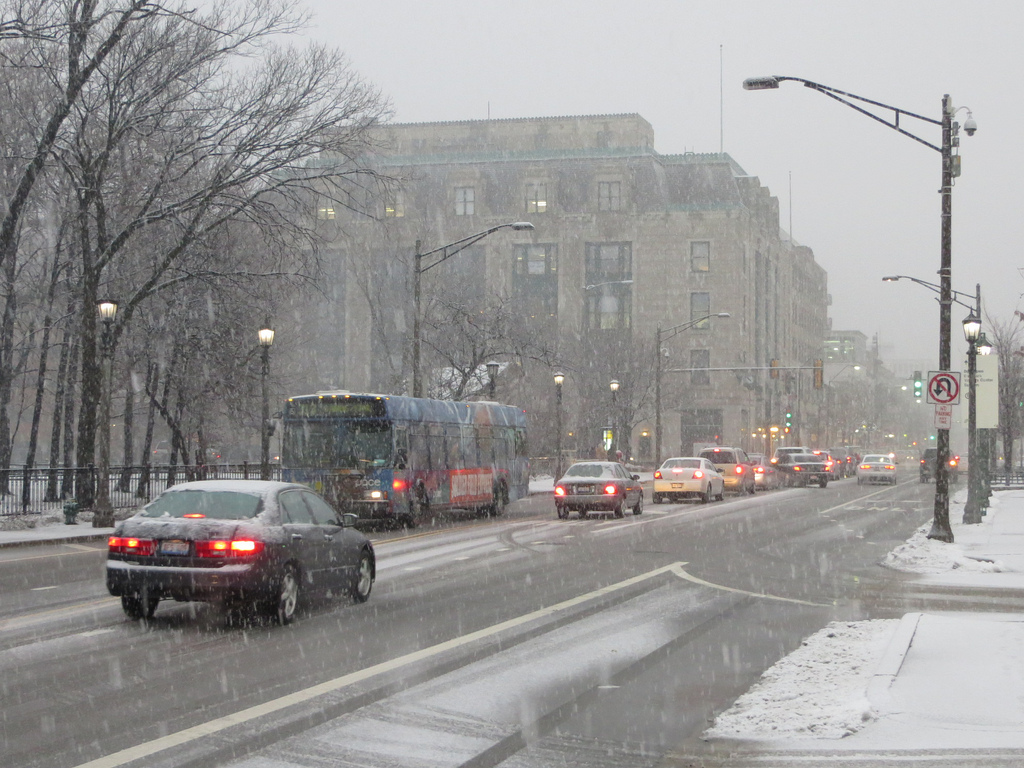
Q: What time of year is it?
A: Wintertime.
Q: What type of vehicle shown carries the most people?
A: Bus.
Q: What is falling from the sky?
A: Snow.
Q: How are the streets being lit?
A: Street lights.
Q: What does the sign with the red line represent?
A: No U turns.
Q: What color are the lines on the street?
A: White.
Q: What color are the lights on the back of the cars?
A: Red.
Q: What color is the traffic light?
A: Green.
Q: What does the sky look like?
A: Grey.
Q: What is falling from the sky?
A: Snow.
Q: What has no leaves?
A: Trees.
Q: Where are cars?
A: In the street.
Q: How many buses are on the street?
A: One.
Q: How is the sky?
A: Overcast.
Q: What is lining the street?
A: Street lamps.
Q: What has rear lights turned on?
A: Cars.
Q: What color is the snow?
A: White.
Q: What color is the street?
A: Gray.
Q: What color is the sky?
A: Gray.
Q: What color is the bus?
A: Blue.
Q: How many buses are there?
A: One.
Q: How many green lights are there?
A: One.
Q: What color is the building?
A: Brown.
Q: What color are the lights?
A: Red.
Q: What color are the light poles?
A: Black.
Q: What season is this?
A: Winter.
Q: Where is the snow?
A: On street.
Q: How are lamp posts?
A: On.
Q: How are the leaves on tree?
A: No leaves.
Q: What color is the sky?
A: Gray.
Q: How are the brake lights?
A: On.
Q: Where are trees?
A: On sidewalk.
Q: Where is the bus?
A: On the street.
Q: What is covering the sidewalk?
A: Snow.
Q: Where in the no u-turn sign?
A: On the lamp post.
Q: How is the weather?
A: Snowy.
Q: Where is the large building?
A: Across the street.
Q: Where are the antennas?
A: On the building.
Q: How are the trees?
A: Bare.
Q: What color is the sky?
A: Grey.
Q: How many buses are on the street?
A: One.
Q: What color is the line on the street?
A: White.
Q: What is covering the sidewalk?
A: Snow.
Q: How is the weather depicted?
A: Snowy, dark and gloomy.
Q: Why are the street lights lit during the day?
A: Because it is snowy, dark and gloomy.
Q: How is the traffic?
A: Moderately heavy.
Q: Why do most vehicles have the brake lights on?
A: To drive slowly on snow.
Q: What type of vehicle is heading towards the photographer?
A: Bus.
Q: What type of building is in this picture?
A: Large, tan brick building.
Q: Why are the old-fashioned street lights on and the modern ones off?
A: Modern ones are on a timer for nighttime.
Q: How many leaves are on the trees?
A: None.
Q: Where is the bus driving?
A: On the street.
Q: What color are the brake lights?
A: Red.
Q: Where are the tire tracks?
A: In the snow.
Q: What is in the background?
A: A large building.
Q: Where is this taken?
A: A city street.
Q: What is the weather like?
A: The weather is snowing.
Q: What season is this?
A: Winter.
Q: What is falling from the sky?
A: Snowflakes.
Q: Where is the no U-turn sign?
A: On the lamp post.